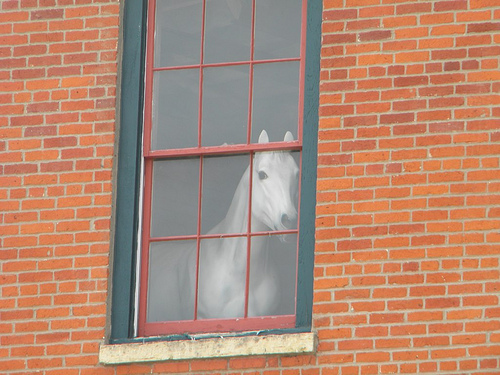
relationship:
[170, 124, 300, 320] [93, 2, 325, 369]
horse in window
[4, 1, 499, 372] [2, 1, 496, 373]
building has wall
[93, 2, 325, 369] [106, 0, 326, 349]
window has frame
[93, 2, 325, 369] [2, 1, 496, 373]
window on wall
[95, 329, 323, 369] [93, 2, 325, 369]
window sill under window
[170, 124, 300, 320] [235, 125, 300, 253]
horse has head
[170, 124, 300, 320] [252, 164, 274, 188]
horse has eye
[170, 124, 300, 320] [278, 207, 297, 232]
horse has nose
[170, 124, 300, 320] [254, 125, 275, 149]
horse has ear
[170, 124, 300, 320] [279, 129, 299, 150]
horse has ear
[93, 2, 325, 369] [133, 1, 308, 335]
window has trim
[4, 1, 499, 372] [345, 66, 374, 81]
building made of brick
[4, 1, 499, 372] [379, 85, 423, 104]
building made of brick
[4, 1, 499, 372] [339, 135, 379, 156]
building made of brick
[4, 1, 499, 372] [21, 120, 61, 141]
building made of brick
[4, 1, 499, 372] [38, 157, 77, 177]
building made of brick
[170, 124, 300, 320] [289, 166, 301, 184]
horse has eye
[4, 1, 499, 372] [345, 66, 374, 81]
building has brick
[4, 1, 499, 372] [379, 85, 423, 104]
building has brick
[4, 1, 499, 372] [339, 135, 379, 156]
building has brick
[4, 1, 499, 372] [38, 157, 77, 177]
building has brick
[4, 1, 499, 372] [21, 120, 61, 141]
building has brick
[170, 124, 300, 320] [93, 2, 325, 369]
horse looking through window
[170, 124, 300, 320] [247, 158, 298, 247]
horse has face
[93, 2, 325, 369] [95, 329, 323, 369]
window has window sill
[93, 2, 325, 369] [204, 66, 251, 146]
window has panel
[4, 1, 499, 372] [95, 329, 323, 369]
building has window sill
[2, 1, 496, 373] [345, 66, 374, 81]
wall has brick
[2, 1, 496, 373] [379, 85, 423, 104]
wall has brick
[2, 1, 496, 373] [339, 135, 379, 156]
wall has brick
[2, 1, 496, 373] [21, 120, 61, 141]
wall has brick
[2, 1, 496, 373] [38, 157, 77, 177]
wall has brick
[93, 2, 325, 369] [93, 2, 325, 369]
window has window